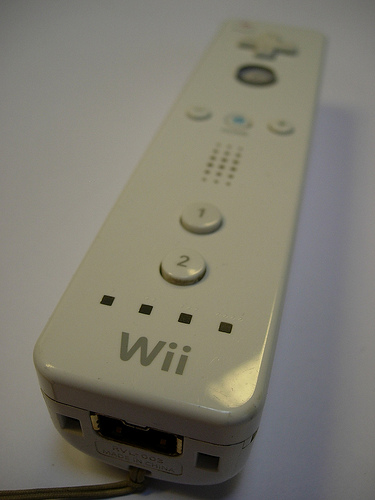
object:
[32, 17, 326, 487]
wii remote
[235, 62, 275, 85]
home button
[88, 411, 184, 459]
usb port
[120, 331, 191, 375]
wii logo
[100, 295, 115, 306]
power light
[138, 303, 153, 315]
power light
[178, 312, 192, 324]
power light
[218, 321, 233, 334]
power light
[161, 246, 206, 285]
button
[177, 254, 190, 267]
number 2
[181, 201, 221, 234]
button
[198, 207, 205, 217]
number 1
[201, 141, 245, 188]
speaker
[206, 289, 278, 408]
light reflection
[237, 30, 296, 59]
directional button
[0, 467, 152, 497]
strap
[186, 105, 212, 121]
minus button